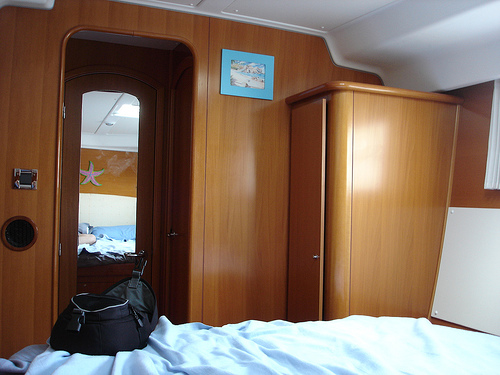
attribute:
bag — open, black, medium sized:
[49, 257, 159, 357]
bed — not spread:
[0, 313, 499, 374]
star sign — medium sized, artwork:
[79, 160, 106, 187]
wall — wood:
[78, 133, 139, 226]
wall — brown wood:
[0, 0, 384, 360]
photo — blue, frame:
[229, 58, 264, 90]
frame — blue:
[220, 48, 275, 101]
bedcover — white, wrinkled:
[24, 314, 499, 374]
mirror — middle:
[78, 88, 140, 295]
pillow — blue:
[91, 225, 137, 240]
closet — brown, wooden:
[285, 80, 464, 322]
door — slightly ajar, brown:
[287, 98, 327, 322]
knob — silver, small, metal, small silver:
[312, 253, 319, 259]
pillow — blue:
[77, 222, 94, 235]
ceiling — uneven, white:
[1, 1, 500, 92]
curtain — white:
[483, 78, 499, 190]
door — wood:
[169, 65, 193, 324]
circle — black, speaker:
[0, 215, 39, 251]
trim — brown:
[1, 214, 40, 252]